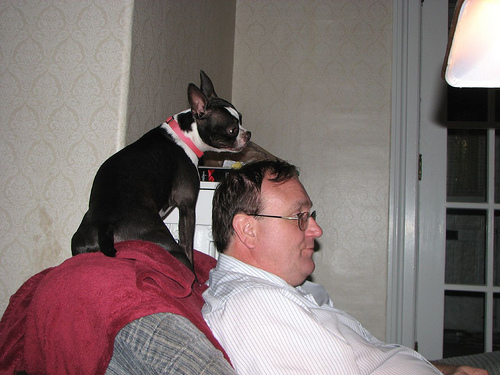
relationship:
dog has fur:
[68, 67, 253, 269] [68, 72, 255, 251]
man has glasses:
[200, 160, 490, 374] [237, 200, 317, 227]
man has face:
[200, 160, 490, 374] [255, 169, 322, 288]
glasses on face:
[237, 200, 317, 227] [255, 169, 322, 288]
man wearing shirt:
[200, 160, 490, 374] [203, 251, 441, 374]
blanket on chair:
[3, 238, 234, 373] [67, 245, 251, 374]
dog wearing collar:
[68, 67, 253, 269] [157, 114, 202, 161]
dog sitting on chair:
[68, 67, 253, 269] [67, 245, 251, 374]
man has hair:
[200, 160, 490, 374] [208, 160, 301, 254]